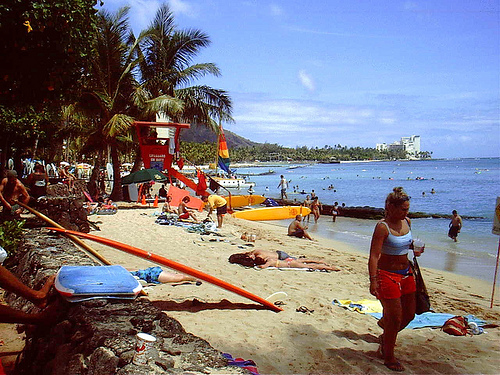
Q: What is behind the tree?
A: Mountains and sky.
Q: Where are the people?
A: On a beach.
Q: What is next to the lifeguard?
A: Many trees.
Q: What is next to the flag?
A: A lifeguard stand.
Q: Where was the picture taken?
A: On a beach.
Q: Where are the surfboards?
A: On the boat docks.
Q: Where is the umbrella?
A: Next to the lifeguard stand.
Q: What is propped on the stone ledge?
A: A surfboard.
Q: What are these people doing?
A: Having fun on the beack.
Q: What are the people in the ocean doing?
A: Swimming.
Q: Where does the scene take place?
A: At the beach.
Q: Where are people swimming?
A: In the ocean.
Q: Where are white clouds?
A: In the sky.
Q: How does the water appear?
A: Calm.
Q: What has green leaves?
A: Many trees.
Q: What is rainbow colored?
A: Sailboat's sail.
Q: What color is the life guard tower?
A: Red.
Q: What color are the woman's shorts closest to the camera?
A: Orange.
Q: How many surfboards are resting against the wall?
A: 2.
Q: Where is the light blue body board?
A: On the wall.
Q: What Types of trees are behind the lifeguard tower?
A: Palm.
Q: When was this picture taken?
A: Daytime.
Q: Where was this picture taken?
A: The beach.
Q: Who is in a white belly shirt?
A: The woman closest to the camera.